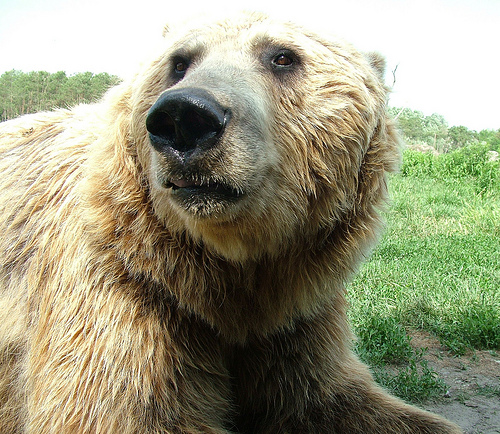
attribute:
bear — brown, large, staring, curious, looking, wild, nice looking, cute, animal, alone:
[1, 10, 460, 434]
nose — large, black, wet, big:
[144, 88, 227, 148]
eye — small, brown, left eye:
[270, 50, 295, 68]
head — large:
[114, 8, 397, 267]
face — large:
[146, 31, 317, 227]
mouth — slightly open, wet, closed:
[162, 169, 233, 204]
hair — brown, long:
[4, 8, 455, 433]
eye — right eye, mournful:
[170, 56, 189, 73]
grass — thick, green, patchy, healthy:
[354, 166, 495, 400]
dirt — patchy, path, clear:
[354, 316, 499, 429]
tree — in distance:
[3, 73, 19, 118]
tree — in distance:
[15, 76, 36, 116]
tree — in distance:
[39, 74, 58, 112]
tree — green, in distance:
[59, 74, 72, 113]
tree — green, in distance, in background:
[84, 76, 96, 103]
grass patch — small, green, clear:
[374, 368, 443, 405]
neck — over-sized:
[106, 74, 376, 323]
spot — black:
[279, 56, 285, 63]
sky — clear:
[1, 2, 500, 138]